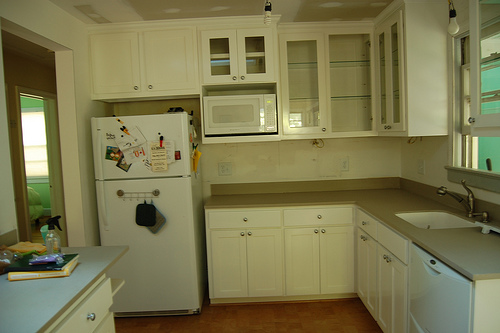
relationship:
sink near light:
[391, 180, 483, 242] [443, 6, 462, 38]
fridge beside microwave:
[85, 110, 203, 316] [201, 92, 282, 137]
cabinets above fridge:
[89, 26, 200, 102] [85, 110, 203, 316]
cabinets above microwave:
[89, 26, 200, 102] [201, 92, 282, 137]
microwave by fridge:
[201, 92, 282, 137] [85, 110, 203, 316]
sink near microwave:
[391, 180, 483, 242] [201, 92, 282, 137]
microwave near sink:
[201, 92, 282, 137] [391, 180, 483, 242]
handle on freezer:
[93, 137, 111, 228] [91, 113, 181, 176]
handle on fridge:
[101, 181, 111, 229] [85, 110, 203, 316]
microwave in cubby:
[201, 92, 282, 137] [196, 81, 286, 136]